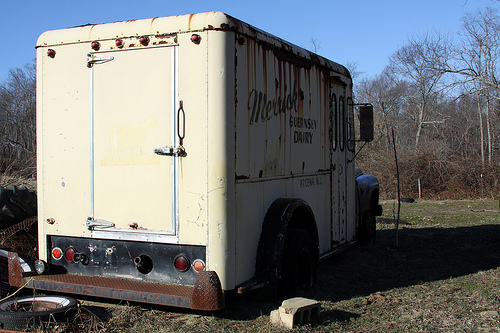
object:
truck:
[7, 8, 387, 312]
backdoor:
[85, 41, 179, 238]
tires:
[260, 196, 321, 295]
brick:
[266, 294, 321, 330]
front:
[354, 164, 385, 241]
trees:
[454, 22, 487, 175]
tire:
[0, 293, 81, 332]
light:
[46, 33, 202, 56]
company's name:
[246, 87, 300, 126]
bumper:
[5, 250, 226, 312]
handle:
[153, 145, 185, 158]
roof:
[35, 9, 355, 80]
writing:
[246, 87, 318, 145]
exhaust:
[133, 254, 154, 275]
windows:
[329, 92, 337, 152]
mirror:
[358, 102, 375, 141]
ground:
[0, 192, 500, 332]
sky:
[0, 0, 500, 105]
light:
[171, 253, 192, 273]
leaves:
[277, 233, 284, 239]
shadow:
[211, 221, 500, 322]